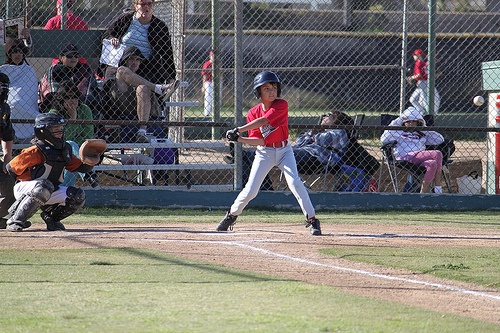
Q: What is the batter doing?
A: Hitting the ball.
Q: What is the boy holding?
A: A baseball bat.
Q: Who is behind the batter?
A: The catcher.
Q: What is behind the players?
A: A chain link fence.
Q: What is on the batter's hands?
A: Gloves.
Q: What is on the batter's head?
A: A baseball helmet.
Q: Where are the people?
A: At a baseball game.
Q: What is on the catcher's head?
A: A helmet.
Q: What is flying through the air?
A: The baseball.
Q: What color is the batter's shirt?
A: Red.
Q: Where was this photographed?
A: Baseball field.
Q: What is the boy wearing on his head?
A: A helmet.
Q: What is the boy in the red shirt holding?
A: A bat.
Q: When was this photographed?
A: Daytime.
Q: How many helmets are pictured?
A: Two.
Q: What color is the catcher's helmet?
A: Black.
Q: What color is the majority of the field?
A: Green.